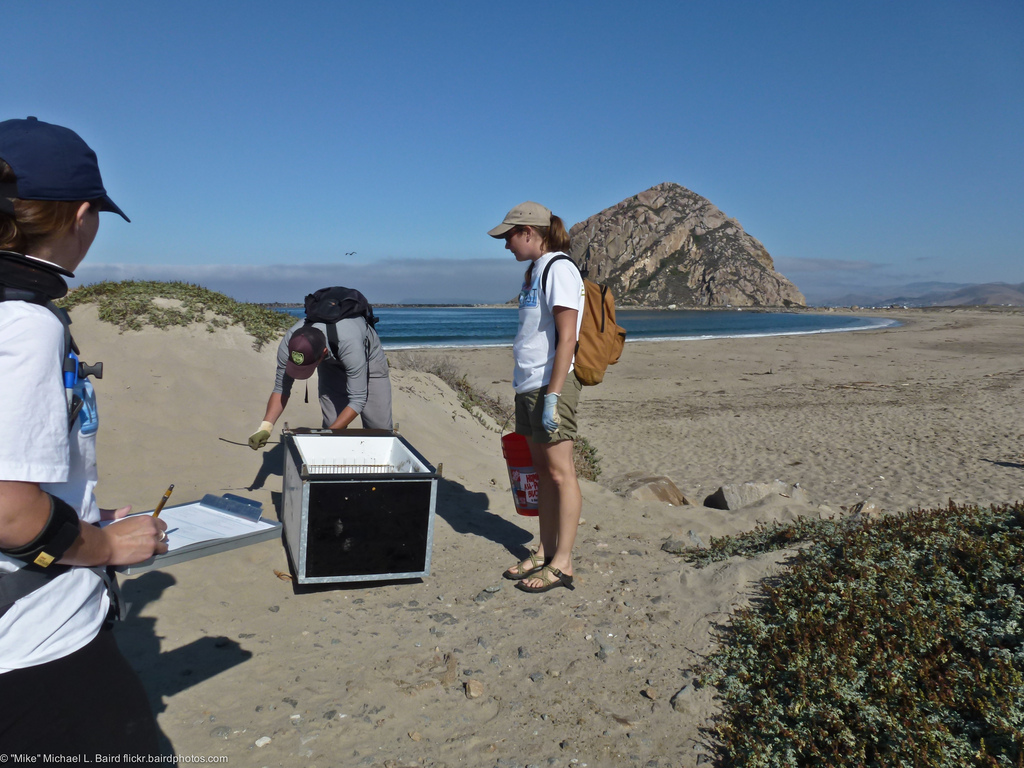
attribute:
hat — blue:
[0, 113, 145, 230]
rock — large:
[538, 162, 794, 323]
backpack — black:
[287, 270, 387, 331]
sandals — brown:
[494, 536, 588, 608]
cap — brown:
[488, 190, 588, 284]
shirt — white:
[505, 247, 586, 390]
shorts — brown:
[503, 357, 583, 451]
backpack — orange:
[570, 258, 637, 403]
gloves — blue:
[525, 368, 565, 446]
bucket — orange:
[497, 409, 571, 526]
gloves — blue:
[536, 392, 576, 434]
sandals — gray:
[505, 530, 588, 593]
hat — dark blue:
[4, 108, 205, 320]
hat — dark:
[278, 312, 326, 390]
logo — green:
[281, 342, 305, 369]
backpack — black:
[298, 275, 392, 345]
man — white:
[250, 290, 402, 414]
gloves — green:
[239, 420, 276, 462]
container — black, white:
[278, 407, 443, 598]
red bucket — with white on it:
[502, 422, 546, 518]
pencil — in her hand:
[148, 478, 185, 520]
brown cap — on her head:
[487, 206, 561, 241]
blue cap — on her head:
[0, 119, 134, 232]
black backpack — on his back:
[304, 279, 384, 366]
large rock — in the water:
[569, 182, 812, 317]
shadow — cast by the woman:
[425, 454, 536, 552]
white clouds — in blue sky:
[200, 135, 475, 200]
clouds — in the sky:
[262, 262, 505, 289]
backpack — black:
[293, 260, 356, 334]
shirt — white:
[1, 309, 110, 601]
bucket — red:
[507, 402, 553, 550]